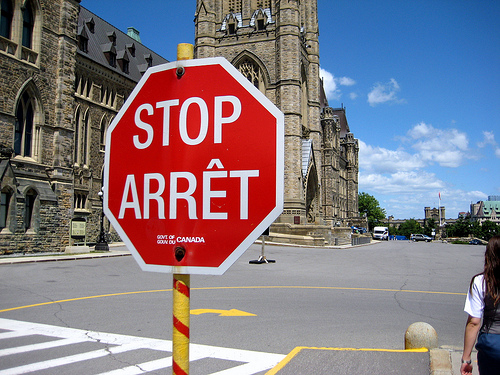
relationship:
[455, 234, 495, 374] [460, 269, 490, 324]
person wearing white shirt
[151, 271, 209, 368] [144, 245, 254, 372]
red stripes on pole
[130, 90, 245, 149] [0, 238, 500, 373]
stop on next to road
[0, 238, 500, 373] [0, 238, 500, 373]
road and road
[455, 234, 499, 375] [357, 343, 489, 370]
person walking down sidewalk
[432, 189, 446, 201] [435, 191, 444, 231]
flag on pole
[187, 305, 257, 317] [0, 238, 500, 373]
arrow painted on road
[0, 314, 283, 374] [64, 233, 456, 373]
lines painted on street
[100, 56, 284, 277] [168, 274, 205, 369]
sign on pole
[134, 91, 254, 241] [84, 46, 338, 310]
lettering on sign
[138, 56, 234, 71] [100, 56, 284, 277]
border on sign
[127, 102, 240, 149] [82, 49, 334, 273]
stop on sign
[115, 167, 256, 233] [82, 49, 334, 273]
arrêt on sign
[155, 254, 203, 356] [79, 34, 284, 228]
pole on sign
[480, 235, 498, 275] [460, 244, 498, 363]
hair on person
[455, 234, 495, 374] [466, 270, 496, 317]
person wearing white shirt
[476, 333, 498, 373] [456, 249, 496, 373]
pants on person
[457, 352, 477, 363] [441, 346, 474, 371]
silver band on wrist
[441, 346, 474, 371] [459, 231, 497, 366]
wrist on person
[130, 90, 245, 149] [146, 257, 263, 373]
stop on pole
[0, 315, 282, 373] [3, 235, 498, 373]
paint on pavement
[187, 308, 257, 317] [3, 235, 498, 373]
arrow on pavement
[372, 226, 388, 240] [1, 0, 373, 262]
bus parked by church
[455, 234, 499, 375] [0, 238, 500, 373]
person walking on road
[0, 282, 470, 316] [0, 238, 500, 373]
line painted on road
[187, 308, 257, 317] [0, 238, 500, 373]
arrow painted on road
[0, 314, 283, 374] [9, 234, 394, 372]
lines marking pavement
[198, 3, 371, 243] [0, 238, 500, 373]
building beside road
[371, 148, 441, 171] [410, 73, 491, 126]
clouds in sky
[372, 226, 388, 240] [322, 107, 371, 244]
bus near building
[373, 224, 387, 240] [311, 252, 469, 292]
bus parked along street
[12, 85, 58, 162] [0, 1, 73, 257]
window along building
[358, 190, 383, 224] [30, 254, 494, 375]
trees growing in distance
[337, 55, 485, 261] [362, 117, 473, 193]
part of a cloud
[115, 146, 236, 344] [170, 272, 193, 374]
part of a pole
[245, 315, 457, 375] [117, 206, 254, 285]
edge of a board